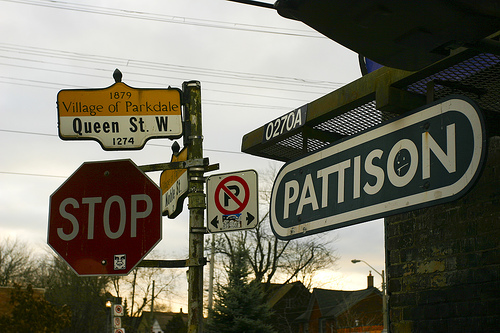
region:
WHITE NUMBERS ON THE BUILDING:
[256, 109, 305, 138]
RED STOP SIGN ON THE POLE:
[49, 160, 163, 273]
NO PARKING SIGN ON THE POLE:
[208, 173, 260, 231]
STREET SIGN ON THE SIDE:
[278, 141, 431, 191]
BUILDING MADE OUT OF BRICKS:
[438, 259, 478, 281]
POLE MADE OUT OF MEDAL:
[188, 85, 203, 331]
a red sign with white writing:
[46, 158, 163, 279]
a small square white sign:
[204, 168, 259, 232]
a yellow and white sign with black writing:
[56, 68, 180, 152]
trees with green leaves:
[0, 158, 345, 332]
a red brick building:
[294, 270, 384, 332]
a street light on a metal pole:
[348, 258, 387, 332]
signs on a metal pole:
[43, 68, 258, 331]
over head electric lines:
[0, 2, 360, 177]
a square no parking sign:
[204, 168, 259, 233]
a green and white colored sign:
[268, 93, 485, 240]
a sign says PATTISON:
[270, 102, 461, 249]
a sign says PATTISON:
[260, 139, 491, 251]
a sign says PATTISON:
[268, 103, 480, 248]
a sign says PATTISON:
[258, 134, 462, 236]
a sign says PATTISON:
[263, 145, 445, 247]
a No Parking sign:
[201, 163, 261, 240]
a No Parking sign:
[200, 168, 265, 240]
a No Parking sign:
[200, 165, 262, 246]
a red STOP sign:
[49, 160, 185, 283]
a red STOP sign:
[42, 162, 169, 279]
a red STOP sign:
[52, 148, 172, 288]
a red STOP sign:
[45, 159, 168, 306]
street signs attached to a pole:
[35, 77, 271, 322]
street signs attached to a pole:
[40, 56, 272, 326]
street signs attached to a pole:
[32, 58, 282, 316]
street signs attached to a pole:
[35, 65, 284, 323]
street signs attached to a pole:
[27, 63, 277, 320]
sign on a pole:
[72, 65, 257, 280]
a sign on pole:
[49, 145, 271, 327]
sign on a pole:
[158, 154, 228, 233]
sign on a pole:
[184, 160, 274, 235]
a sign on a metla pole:
[64, 69, 175, 138]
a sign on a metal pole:
[134, 138, 215, 211]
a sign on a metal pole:
[193, 165, 285, 248]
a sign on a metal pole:
[33, 163, 236, 306]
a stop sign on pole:
[51, 170, 231, 292]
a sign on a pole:
[47, 143, 229, 327]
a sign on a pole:
[61, 55, 311, 223]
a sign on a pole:
[129, 130, 204, 229]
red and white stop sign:
[41, 155, 167, 280]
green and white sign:
[266, 88, 488, 245]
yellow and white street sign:
[52, 65, 186, 153]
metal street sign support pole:
[174, 75, 214, 331]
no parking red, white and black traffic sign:
[200, 165, 264, 241]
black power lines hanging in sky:
[3, 1, 361, 204]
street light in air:
[345, 255, 389, 332]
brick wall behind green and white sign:
[377, 86, 499, 331]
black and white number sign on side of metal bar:
[258, 100, 311, 147]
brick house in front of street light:
[291, 265, 384, 332]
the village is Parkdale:
[120, 98, 178, 119]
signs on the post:
[78, 82, 250, 273]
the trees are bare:
[216, 223, 332, 288]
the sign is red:
[57, 161, 157, 286]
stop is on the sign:
[59, 195, 147, 247]